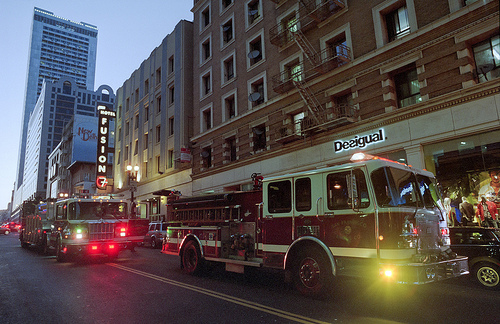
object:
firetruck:
[21, 196, 128, 261]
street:
[0, 230, 396, 324]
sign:
[334, 129, 388, 153]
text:
[93, 103, 117, 191]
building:
[13, 2, 99, 222]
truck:
[166, 159, 466, 288]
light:
[379, 266, 397, 277]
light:
[91, 245, 116, 254]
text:
[325, 131, 401, 146]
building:
[193, 0, 500, 262]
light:
[73, 227, 84, 235]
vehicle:
[444, 223, 497, 287]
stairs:
[272, 0, 362, 137]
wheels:
[37, 234, 68, 258]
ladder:
[168, 205, 243, 223]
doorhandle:
[314, 196, 326, 221]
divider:
[96, 261, 310, 318]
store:
[192, 111, 499, 218]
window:
[422, 153, 500, 228]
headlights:
[391, 194, 468, 286]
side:
[165, 186, 466, 283]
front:
[66, 199, 129, 251]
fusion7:
[96, 104, 110, 190]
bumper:
[58, 237, 134, 245]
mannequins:
[443, 189, 496, 226]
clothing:
[444, 199, 499, 227]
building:
[114, 20, 193, 231]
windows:
[379, 66, 435, 101]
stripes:
[115, 21, 191, 182]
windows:
[167, 150, 175, 168]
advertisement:
[72, 113, 108, 160]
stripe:
[106, 261, 325, 321]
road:
[6, 238, 461, 319]